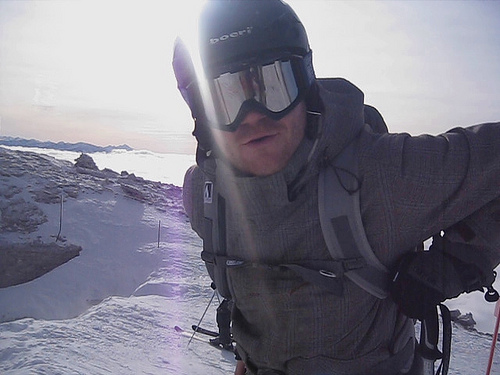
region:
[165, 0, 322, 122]
Man wearing a helmet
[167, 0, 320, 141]
Man is wearing a helmet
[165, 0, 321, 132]
Man wearing a black helmet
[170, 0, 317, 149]
Man is wearing a black helmet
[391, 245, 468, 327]
Man wearing gloves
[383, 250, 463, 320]
Man is wearing gloves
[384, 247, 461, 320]
Man wearing black gloves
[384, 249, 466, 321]
Man is wearing black gloves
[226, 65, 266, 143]
There is a pair of glasses this man is wearing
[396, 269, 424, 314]
This man is wearing a pair of black gloves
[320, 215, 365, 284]
This man is carrying a backpack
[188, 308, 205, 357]
This person is holding a ski pole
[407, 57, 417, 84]
There is some light blue sky visible here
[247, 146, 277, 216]
This man is sporting stubble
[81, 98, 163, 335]
Jackson Mingus took this photo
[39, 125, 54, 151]
There are mountain peaks in the distance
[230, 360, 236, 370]
There is a red ski pole visible here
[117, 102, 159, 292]
This photo was taken in Colorado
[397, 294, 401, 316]
part of a glove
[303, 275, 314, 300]
part of a sweater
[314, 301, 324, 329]
edge of a shoulder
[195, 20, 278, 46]
Person wearing black helmet.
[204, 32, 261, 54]
Silver writing on front of helmet.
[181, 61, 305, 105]
Person wearing goggles on face.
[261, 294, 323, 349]
Person wearing gray coat.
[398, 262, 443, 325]
Person wearing black glove.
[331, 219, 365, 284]
Gray strap around man's shoulder.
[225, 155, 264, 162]
Man has scruff on face.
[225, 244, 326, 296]
Black strap connecting 2 gray straps.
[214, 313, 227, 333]
Person wearing black pants.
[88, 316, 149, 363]
Ground is covered in snow.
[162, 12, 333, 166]
man wearing a helmet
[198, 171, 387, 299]
backpack straps across the chest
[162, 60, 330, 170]
man wearing goggles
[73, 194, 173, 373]
white snow on the ground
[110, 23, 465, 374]
man standing in snow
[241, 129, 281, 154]
lips on a man's face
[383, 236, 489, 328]
left hand covered with a glove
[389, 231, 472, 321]
black hand glove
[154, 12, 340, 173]
man wearing a helmet and goggles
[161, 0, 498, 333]
person carrying a backpack